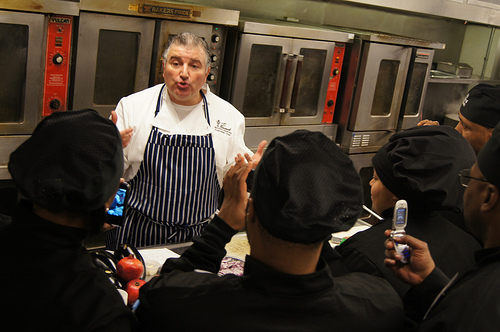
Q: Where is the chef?
A: Behind the counter.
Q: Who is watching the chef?
A: Students.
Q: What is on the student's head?
A: Hat.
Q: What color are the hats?
A: Black.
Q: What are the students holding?
A: Phone.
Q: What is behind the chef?
A: Ovens.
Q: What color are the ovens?
A: Gray.